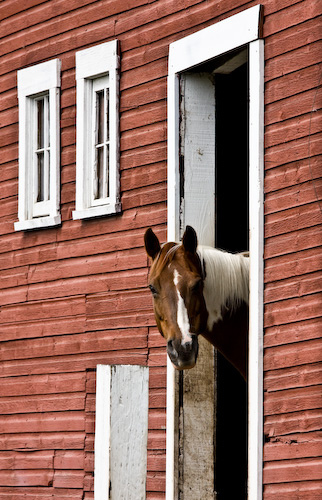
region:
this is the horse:
[140, 237, 242, 364]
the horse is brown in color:
[139, 226, 252, 368]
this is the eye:
[147, 281, 155, 295]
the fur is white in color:
[212, 255, 237, 287]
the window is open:
[164, 409, 256, 477]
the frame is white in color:
[218, 20, 249, 43]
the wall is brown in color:
[0, 241, 121, 330]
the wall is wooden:
[0, 246, 116, 338]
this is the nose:
[167, 337, 194, 351]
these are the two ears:
[141, 220, 197, 253]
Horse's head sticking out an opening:
[139, 224, 247, 366]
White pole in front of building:
[92, 360, 149, 492]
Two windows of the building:
[5, 33, 120, 228]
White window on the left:
[8, 56, 54, 228]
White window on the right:
[70, 33, 119, 219]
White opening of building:
[159, 23, 268, 497]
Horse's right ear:
[138, 223, 161, 261]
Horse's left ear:
[175, 218, 198, 251]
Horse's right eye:
[142, 277, 161, 293]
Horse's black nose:
[164, 332, 202, 356]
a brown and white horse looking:
[141, 225, 250, 369]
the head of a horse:
[142, 223, 205, 366]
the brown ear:
[143, 223, 162, 261]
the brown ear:
[181, 225, 199, 252]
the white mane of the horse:
[198, 244, 249, 307]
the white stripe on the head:
[171, 267, 191, 347]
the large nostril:
[165, 338, 177, 355]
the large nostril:
[187, 332, 200, 357]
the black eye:
[146, 282, 157, 293]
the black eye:
[191, 279, 202, 294]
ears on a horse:
[141, 224, 202, 265]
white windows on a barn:
[12, 43, 132, 232]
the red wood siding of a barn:
[16, 248, 138, 353]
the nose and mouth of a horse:
[161, 331, 204, 371]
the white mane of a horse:
[197, 235, 260, 327]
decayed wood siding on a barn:
[260, 427, 302, 451]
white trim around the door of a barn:
[159, 10, 275, 138]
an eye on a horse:
[143, 281, 161, 303]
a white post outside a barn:
[78, 358, 162, 497]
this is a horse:
[142, 221, 258, 387]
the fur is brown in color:
[175, 255, 198, 270]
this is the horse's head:
[139, 223, 208, 377]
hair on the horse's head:
[199, 252, 256, 303]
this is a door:
[169, 46, 249, 482]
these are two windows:
[12, 41, 122, 228]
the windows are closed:
[22, 130, 114, 205]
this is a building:
[7, 42, 321, 489]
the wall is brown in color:
[291, 192, 317, 215]